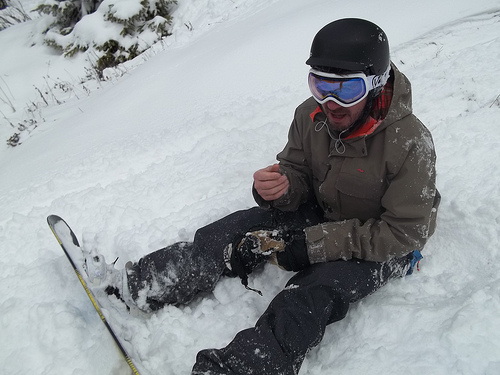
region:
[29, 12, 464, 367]
a snowboarder sitting on the snow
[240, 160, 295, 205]
the hand of a man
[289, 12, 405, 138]
the head of a man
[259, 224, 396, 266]
the arm of a man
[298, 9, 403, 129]
a man wearing ski goggles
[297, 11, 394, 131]
a man with a beard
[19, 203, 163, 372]
a snowboard lying on its side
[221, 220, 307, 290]
the glove of a snowboarder holding the other glove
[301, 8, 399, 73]
a black ski helmet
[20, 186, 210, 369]
his snowboard is covered in snow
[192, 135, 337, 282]
he took his glove off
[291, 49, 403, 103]
a pair of white googles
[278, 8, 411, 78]
this is a black helmet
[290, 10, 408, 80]
this helmet is black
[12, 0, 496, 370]
he is a snowboarder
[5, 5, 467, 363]
he is sitting in the snow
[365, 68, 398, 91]
this is the Von Zipper logo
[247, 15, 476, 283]
his jacket is grey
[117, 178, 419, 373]
his pants are black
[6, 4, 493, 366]
winter scene with a lot of snow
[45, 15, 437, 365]
snowboard rider sitting in the show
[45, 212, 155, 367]
yellow and black snow board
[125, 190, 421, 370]
black leggings on a snow boarder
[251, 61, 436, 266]
gray jacket with a hood on a snow boarder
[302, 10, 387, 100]
black helmet with blue lens goggles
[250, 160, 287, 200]
right hand of a skate boarder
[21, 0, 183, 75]
pine tree on the side of a slope covered with snow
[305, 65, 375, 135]
face of a skate boarder with a beard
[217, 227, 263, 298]
black glove held in a left hand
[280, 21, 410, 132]
head of a person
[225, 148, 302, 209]
hand of a person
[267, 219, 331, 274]
hand of a person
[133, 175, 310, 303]
leg of a person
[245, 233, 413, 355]
leg of a person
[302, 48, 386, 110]
eye of a person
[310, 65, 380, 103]
goggle of a person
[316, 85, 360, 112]
nose of a person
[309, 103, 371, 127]
mouth of a person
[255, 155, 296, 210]
fingers of a person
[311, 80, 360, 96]
clear space on goggles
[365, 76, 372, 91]
white lining on goggles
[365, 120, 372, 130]
red inside of hoody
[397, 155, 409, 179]
man wearing greenish jacket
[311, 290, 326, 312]
man wearing blue pants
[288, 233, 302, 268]
man wearing black gloves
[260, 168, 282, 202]
mans naked bare hand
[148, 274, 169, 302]
snow on man's pants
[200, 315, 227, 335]
snow inbetween man's legs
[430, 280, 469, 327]
white snow on ground